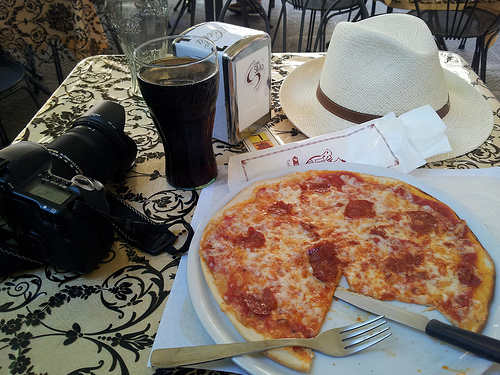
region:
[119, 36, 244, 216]
a glass on the table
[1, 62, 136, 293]
a camera on a table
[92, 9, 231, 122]
an empty glass on table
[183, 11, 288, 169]
a napkin dispenser on table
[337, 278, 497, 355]
knife on plate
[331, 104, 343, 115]
BROWN BAND AROUND HAT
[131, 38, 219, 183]
GLASS OF SODA ON THE TABLE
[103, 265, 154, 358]
PRINT ON THE CLOTH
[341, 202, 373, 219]
MEAT ON THE PIZZA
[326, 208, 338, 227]
CHEESE ON THE PIZZA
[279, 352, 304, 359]
CRUST OF PIZZA VERY THIN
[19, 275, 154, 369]
the table is paisley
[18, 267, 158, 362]
the design is black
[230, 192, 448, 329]
the cheese is melted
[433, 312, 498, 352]
knife handle is black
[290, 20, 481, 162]
hat on the table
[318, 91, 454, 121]
band around the hat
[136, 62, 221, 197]
cola in the glass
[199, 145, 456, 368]
a pizza on a white plate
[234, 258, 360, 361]
a slice of pizza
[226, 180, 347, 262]
a slice of pizza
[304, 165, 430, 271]
a slice of pizza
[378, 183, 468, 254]
a slice of pizza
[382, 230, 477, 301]
a slice of pizza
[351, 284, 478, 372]
a knife on a plate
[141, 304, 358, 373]
a fork on a plate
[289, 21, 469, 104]
hat sitting on the table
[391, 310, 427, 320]
knife on the table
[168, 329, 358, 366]
fork on the table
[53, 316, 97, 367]
table cloth on the table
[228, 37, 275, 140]
napkin holder on the table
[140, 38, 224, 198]
glass on the table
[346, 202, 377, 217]
meat on top of pizza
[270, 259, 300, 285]
cheese on top of pizza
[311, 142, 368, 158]
paper sack on the table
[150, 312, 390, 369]
a metal dinner fork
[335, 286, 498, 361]
a black handle steak knife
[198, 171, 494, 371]
a pepperoni and cheese pizza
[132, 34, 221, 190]
a class of dark soda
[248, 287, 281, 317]
pepperoni on the pizza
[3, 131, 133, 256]
a camera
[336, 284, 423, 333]
a knife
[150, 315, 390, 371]
the fork on the plate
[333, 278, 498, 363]
the knife on the plate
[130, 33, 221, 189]
the glass on the table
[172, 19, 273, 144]
the silver napkin folder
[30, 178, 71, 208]
the display of the camera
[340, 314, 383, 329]
the silver fork prong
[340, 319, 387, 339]
the silver prong of the fork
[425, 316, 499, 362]
the black handle of the knife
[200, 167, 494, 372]
the pizza on the plate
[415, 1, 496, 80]
the black chair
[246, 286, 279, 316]
the pepperoni on the pizza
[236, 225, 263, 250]
the pepperoni on the pizza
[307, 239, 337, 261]
the pepperoni on the pizza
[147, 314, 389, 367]
the silver fork on the plate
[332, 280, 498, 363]
the silver knife on the plate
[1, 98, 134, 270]
the camera on the table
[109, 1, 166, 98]
the empty glass on the table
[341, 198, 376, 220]
the pepperoni on the pizza